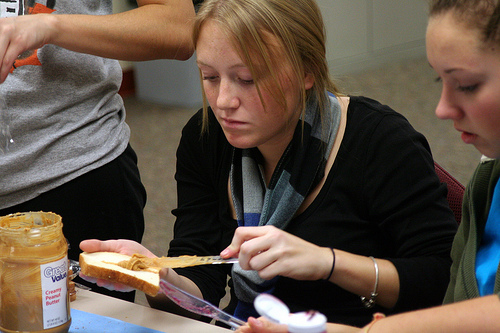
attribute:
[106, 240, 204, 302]
butter — peanut 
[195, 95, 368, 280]
scarf — gray and black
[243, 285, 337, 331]
lid — open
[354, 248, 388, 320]
bracelet — silver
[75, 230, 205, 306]
peanut butter — on bread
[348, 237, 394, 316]
bracelet — silver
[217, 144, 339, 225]
scarf — grey black and blue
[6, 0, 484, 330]
three people — making a sandwich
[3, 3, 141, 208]
t-shirt — grey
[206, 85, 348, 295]
scarf — tied around woman's neck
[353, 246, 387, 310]
bracelet — on her left arm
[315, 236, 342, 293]
band — around her left arm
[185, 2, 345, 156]
woman hair — dark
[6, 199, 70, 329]
peanut butter — on the table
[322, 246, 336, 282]
band — black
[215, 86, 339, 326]
showl — multicolored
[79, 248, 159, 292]
bread — slice, white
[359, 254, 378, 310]
wristband — shiny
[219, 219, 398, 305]
arm — left arm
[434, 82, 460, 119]
nose — sharp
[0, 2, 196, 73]
arm — man's arm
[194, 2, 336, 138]
hair — blonde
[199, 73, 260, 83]
eyelashes — dark blonde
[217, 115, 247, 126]
mouth — without lipstick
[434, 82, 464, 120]
nose — upturned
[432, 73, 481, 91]
eyelashes — long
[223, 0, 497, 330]
woman — dark blonde, dark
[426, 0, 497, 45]
hair — curly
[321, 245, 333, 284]
bracelet — black, rubber, hippie bracelet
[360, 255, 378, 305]
bracelet — silver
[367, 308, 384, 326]
bracelet — salmon colored, rope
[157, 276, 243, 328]
knife — clear, plastic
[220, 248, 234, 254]
fingernails — unpolished